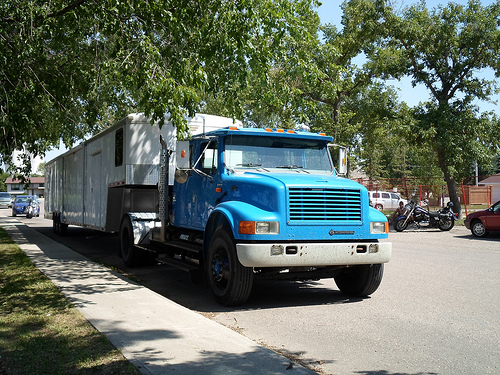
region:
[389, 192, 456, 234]
two wheeled motorcycle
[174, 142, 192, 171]
side view mirror of a large truck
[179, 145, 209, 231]
passenger side door of a truck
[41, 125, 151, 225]
larger trailer to store things in while moving them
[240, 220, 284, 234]
front headlights on a truck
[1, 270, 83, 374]
grass next to a sidewalk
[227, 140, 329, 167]
front window of a truck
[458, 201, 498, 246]
front driver's side of a red car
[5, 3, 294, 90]
leaves on a tree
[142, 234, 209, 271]
steps on a truck used to reach the door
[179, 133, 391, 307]
The cab of a blue truck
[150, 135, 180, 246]
A smokestack on a truck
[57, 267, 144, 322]
A tree is casting a shadow on the sidewalk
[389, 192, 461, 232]
A motorcycle parked on the street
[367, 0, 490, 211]
A tree growing by the street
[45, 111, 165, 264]
A trailer that is attached to a truck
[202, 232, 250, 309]
A front tire on a truck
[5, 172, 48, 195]
A house with a brown roof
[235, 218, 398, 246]
Headlights on the front of a truck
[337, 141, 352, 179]
The side mirror on a truck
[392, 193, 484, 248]
this is a motorcycle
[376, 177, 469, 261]
A person is sitting next to the motorcycle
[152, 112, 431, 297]
this truck cab is blue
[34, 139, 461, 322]
this truck is pulling an enclosed trailor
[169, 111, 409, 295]
no one is inside of the truck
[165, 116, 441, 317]
the lights on this truck are turned off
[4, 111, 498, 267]
trees lines the sides of the street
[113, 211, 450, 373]
this street is made of asphalt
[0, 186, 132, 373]
A sidewalk lines the edges of the street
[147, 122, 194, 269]
this is an exhaust pipe for the truck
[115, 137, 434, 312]
"The truck is blue"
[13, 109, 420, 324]
"The truck is pulling a huge trailer"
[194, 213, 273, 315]
"A big tire for a big truck"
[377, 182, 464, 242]
"A motorcycle is parked"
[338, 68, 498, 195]
"Trees are shown here"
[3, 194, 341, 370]
"The trees shadows are shown"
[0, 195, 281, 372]
"The sidewalk is seen here"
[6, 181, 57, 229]
"A car and motorcycle"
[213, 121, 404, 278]
"The truck has a white front bumper"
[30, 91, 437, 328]
The truck is parked"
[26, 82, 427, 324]
a blue truck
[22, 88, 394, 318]
a blue truck towing a white trailer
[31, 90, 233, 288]
a white trailer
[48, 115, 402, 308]
a white trailer being towed by a blue truck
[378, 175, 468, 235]
a black motorcycle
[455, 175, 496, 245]
a red vehicle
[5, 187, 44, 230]
a blue vehicle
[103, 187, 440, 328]
black tires on a blue truck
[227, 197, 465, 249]
orange lights on a blue truck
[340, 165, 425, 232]
a white vehicle